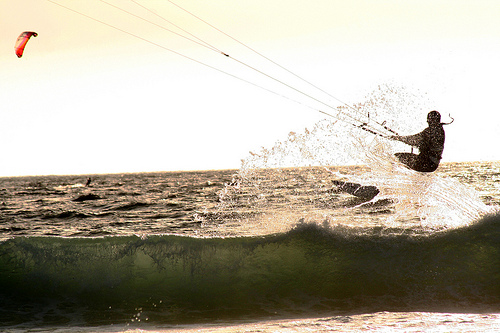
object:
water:
[18, 180, 94, 204]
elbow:
[403, 138, 424, 144]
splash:
[364, 174, 437, 208]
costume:
[394, 128, 450, 175]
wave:
[315, 197, 413, 253]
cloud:
[287, 0, 346, 42]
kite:
[10, 28, 49, 60]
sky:
[105, 55, 139, 69]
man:
[371, 107, 460, 205]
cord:
[174, 0, 407, 137]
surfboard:
[329, 172, 429, 204]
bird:
[49, 170, 93, 189]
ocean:
[52, 164, 262, 324]